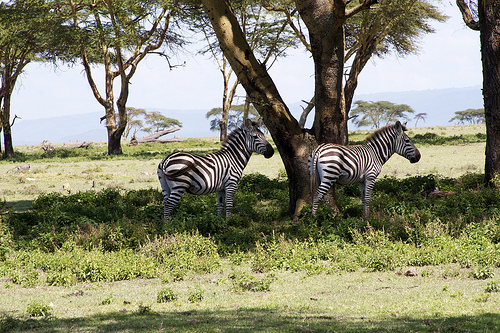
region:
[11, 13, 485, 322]
2 zebras on the African plain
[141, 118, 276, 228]
1 zebra enjoying the shade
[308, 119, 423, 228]
1 zebra enjoying the cool shade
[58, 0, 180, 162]
tall tree with lush green leaves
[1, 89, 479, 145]
mountain line in the back ground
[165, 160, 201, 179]
black tail of zebra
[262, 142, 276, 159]
black nose of zebra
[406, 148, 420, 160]
brown nose of zebra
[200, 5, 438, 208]
tree that is shading zebras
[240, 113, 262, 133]
one set of zebra ears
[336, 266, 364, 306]
part of a ground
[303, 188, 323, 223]
part of a leg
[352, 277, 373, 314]
part of a ground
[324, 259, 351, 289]
part of a ground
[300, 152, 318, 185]
part o fa tail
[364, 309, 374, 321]
part of a shade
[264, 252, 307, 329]
part of a ground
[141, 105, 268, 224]
black and white striped zebra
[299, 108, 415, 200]
black and white striped zebra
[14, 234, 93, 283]
long green and brown grass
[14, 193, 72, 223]
long green and brown grass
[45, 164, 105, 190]
long green and brown grass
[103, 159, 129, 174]
long green and brown grass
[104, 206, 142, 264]
long green and brown grass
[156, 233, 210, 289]
long green and brown grass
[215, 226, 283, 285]
long green and brown grass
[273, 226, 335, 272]
long green and brown grass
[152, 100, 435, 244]
two black and white zebras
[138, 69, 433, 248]
two zebras walking on the grass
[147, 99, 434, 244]
two zebras walking around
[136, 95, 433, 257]
two zebra near a tree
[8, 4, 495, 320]
two zebras in the wild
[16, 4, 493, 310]
two zebras following one another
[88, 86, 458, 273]
two zebras in line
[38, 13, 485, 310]
two zebras with stripes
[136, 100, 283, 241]
zebra head turned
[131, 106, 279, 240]
zebra wagging its tail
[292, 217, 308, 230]
part of a plain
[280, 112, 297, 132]
part of a tree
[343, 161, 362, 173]
part of a zebra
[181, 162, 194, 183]
back of a zebra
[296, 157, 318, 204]
tail of a zebra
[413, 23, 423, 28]
part of a bush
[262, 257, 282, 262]
edge of a lawn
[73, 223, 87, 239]
part of a plain